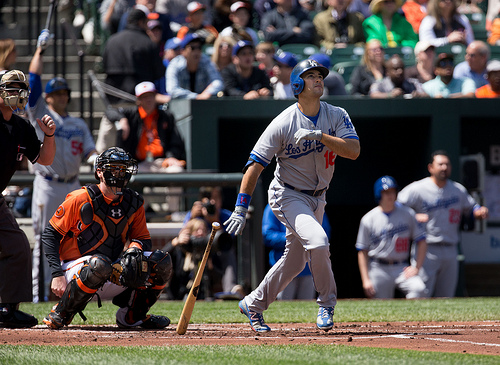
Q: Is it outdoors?
A: Yes, it is outdoors.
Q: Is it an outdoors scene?
A: Yes, it is outdoors.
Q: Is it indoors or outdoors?
A: It is outdoors.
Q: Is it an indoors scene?
A: No, it is outdoors.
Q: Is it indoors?
A: No, it is outdoors.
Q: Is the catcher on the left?
A: Yes, the catcher is on the left of the image.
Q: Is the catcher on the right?
A: No, the catcher is on the left of the image.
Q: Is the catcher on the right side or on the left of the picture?
A: The catcher is on the left of the image.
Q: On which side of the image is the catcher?
A: The catcher is on the left of the image.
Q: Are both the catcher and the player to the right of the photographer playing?
A: Yes, both the catcher and the player are playing.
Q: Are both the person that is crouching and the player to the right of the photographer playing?
A: Yes, both the catcher and the player are playing.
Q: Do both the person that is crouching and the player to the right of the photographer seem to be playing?
A: Yes, both the catcher and the player are playing.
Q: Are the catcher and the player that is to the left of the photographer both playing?
A: Yes, both the catcher and the player are playing.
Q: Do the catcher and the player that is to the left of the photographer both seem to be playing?
A: Yes, both the catcher and the player are playing.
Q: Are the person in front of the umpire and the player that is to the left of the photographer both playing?
A: Yes, both the catcher and the player are playing.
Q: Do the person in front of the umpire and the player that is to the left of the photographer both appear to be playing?
A: Yes, both the catcher and the player are playing.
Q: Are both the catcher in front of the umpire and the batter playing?
A: Yes, both the catcher and the batter are playing.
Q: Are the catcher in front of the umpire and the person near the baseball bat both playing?
A: Yes, both the catcher and the batter are playing.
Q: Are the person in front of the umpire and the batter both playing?
A: Yes, both the catcher and the batter are playing.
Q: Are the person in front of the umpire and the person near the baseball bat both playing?
A: Yes, both the catcher and the batter are playing.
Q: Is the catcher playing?
A: Yes, the catcher is playing.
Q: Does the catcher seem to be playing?
A: Yes, the catcher is playing.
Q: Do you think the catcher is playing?
A: Yes, the catcher is playing.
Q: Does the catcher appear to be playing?
A: Yes, the catcher is playing.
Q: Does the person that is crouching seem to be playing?
A: Yes, the catcher is playing.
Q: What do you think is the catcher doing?
A: The catcher is playing.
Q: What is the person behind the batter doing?
A: The catcher is playing.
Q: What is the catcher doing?
A: The catcher is playing.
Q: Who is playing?
A: The catcher is playing.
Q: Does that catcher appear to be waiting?
A: No, the catcher is playing.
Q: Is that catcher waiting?
A: No, the catcher is playing.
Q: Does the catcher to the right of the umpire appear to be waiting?
A: No, the catcher is playing.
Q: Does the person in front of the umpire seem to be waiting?
A: No, the catcher is playing.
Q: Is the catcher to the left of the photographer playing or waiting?
A: The catcher is playing.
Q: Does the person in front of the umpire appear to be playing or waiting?
A: The catcher is playing.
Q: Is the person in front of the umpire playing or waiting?
A: The catcher is playing.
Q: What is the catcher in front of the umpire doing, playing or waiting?
A: The catcher is playing.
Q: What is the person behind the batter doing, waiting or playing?
A: The catcher is playing.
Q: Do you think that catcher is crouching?
A: Yes, the catcher is crouching.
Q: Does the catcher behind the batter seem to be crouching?
A: Yes, the catcher is crouching.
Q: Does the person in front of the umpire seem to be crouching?
A: Yes, the catcher is crouching.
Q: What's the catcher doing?
A: The catcher is crouching.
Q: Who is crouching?
A: The catcher is crouching.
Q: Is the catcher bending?
A: No, the catcher is crouching.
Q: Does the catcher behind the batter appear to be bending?
A: No, the catcher is crouching.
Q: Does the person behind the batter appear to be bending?
A: No, the catcher is crouching.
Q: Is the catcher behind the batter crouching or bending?
A: The catcher is crouching.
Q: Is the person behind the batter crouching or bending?
A: The catcher is crouching.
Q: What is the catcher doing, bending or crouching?
A: The catcher is crouching.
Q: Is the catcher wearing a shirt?
A: Yes, the catcher is wearing a shirt.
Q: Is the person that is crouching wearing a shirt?
A: Yes, the catcher is wearing a shirt.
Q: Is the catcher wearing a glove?
A: No, the catcher is wearing a shirt.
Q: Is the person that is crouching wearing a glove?
A: No, the catcher is wearing a shirt.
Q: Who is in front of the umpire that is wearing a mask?
A: The catcher is in front of the umpire.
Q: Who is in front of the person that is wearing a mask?
A: The catcher is in front of the umpire.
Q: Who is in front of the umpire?
A: The catcher is in front of the umpire.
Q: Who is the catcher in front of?
A: The catcher is in front of the umpire.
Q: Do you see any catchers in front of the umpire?
A: Yes, there is a catcher in front of the umpire.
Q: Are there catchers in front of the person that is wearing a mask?
A: Yes, there is a catcher in front of the umpire.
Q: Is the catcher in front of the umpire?
A: Yes, the catcher is in front of the umpire.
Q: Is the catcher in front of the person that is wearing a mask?
A: Yes, the catcher is in front of the umpire.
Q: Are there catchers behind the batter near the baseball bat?
A: Yes, there is a catcher behind the batter.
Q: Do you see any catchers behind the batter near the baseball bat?
A: Yes, there is a catcher behind the batter.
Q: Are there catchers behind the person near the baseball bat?
A: Yes, there is a catcher behind the batter.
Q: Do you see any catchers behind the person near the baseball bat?
A: Yes, there is a catcher behind the batter.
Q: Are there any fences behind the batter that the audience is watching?
A: No, there is a catcher behind the batter.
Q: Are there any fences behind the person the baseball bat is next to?
A: No, there is a catcher behind the batter.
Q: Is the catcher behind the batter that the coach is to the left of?
A: Yes, the catcher is behind the batter.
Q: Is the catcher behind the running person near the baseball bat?
A: Yes, the catcher is behind the batter.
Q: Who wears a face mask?
A: The catcher wears a face mask.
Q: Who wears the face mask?
A: The catcher wears a face mask.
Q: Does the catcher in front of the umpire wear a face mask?
A: Yes, the catcher wears a face mask.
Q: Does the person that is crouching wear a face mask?
A: Yes, the catcher wears a face mask.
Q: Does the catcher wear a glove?
A: No, the catcher wears a face mask.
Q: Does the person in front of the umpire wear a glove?
A: No, the catcher wears a face mask.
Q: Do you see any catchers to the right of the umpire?
A: Yes, there is a catcher to the right of the umpire.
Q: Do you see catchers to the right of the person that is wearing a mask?
A: Yes, there is a catcher to the right of the umpire.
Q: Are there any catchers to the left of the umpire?
A: No, the catcher is to the right of the umpire.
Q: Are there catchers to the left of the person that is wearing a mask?
A: No, the catcher is to the right of the umpire.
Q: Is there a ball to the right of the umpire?
A: No, there is a catcher to the right of the umpire.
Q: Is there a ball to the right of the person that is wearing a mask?
A: No, there is a catcher to the right of the umpire.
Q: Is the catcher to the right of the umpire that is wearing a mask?
A: Yes, the catcher is to the right of the umpire.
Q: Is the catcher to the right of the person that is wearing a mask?
A: Yes, the catcher is to the right of the umpire.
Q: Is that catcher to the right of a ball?
A: No, the catcher is to the right of the umpire.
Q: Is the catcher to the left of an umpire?
A: No, the catcher is to the right of an umpire.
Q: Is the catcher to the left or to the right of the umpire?
A: The catcher is to the right of the umpire.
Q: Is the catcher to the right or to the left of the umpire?
A: The catcher is to the right of the umpire.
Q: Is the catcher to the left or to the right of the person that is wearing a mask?
A: The catcher is to the right of the umpire.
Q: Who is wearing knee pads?
A: The catcher is wearing knee pads.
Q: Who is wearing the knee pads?
A: The catcher is wearing knee pads.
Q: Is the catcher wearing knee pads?
A: Yes, the catcher is wearing knee pads.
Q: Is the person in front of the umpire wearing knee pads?
A: Yes, the catcher is wearing knee pads.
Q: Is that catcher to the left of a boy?
A: No, the catcher is to the left of a photographer.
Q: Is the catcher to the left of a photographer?
A: Yes, the catcher is to the left of a photographer.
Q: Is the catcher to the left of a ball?
A: No, the catcher is to the left of a photographer.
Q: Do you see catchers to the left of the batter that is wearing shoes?
A: Yes, there is a catcher to the left of the batter.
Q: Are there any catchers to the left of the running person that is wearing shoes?
A: Yes, there is a catcher to the left of the batter.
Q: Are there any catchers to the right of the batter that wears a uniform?
A: No, the catcher is to the left of the batter.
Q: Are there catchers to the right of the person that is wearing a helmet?
A: No, the catcher is to the left of the batter.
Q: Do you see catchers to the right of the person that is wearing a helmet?
A: No, the catcher is to the left of the batter.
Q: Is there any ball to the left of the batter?
A: No, there is a catcher to the left of the batter.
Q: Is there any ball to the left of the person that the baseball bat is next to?
A: No, there is a catcher to the left of the batter.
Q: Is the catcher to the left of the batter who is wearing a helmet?
A: Yes, the catcher is to the left of the batter.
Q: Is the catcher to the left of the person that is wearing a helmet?
A: Yes, the catcher is to the left of the batter.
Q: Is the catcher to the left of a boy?
A: No, the catcher is to the left of the batter.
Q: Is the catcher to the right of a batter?
A: No, the catcher is to the left of a batter.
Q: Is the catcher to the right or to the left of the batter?
A: The catcher is to the left of the batter.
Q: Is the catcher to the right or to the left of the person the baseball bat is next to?
A: The catcher is to the left of the batter.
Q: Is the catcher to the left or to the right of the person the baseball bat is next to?
A: The catcher is to the left of the batter.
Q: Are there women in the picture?
A: Yes, there is a woman.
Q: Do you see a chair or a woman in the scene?
A: Yes, there is a woman.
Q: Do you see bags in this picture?
A: No, there are no bags.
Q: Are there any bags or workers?
A: No, there are no bags or workers.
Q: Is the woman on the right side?
A: Yes, the woman is on the right of the image.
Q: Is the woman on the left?
A: No, the woman is on the right of the image.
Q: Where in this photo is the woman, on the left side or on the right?
A: The woman is on the right of the image.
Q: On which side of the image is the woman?
A: The woman is on the right of the image.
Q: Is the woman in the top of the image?
A: Yes, the woman is in the top of the image.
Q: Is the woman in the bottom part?
A: No, the woman is in the top of the image.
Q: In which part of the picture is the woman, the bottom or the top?
A: The woman is in the top of the image.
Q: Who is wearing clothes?
A: The woman is wearing clothes.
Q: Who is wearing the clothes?
A: The woman is wearing clothes.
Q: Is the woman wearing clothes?
A: Yes, the woman is wearing clothes.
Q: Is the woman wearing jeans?
A: No, the woman is wearing clothes.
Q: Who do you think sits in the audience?
A: The woman sits in the audience.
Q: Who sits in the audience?
A: The woman sits in the audience.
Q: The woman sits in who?
A: The woman sits in the audience.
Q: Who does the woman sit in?
A: The woman sits in the audience.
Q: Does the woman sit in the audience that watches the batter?
A: Yes, the woman sits in the audience.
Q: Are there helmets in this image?
A: Yes, there is a helmet.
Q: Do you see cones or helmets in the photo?
A: Yes, there is a helmet.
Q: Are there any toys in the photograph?
A: No, there are no toys.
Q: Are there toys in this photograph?
A: No, there are no toys.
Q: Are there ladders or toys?
A: No, there are no toys or ladders.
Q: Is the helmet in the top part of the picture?
A: Yes, the helmet is in the top of the image.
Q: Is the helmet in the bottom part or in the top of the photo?
A: The helmet is in the top of the image.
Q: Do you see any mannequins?
A: No, there are no mannequins.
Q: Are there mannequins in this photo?
A: No, there are no mannequins.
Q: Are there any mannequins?
A: No, there are no mannequins.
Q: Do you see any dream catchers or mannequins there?
A: No, there are no mannequins or dream catchers.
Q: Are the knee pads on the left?
A: Yes, the knee pads are on the left of the image.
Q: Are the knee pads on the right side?
A: No, the knee pads are on the left of the image.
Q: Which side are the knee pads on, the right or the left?
A: The knee pads are on the left of the image.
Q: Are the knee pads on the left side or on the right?
A: The knee pads are on the left of the image.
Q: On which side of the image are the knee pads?
A: The knee pads are on the left of the image.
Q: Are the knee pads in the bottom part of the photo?
A: Yes, the knee pads are in the bottom of the image.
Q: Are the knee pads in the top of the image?
A: No, the knee pads are in the bottom of the image.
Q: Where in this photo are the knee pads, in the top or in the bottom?
A: The knee pads are in the bottom of the image.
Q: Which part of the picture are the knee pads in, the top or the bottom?
A: The knee pads are in the bottom of the image.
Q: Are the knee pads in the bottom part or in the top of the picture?
A: The knee pads are in the bottom of the image.